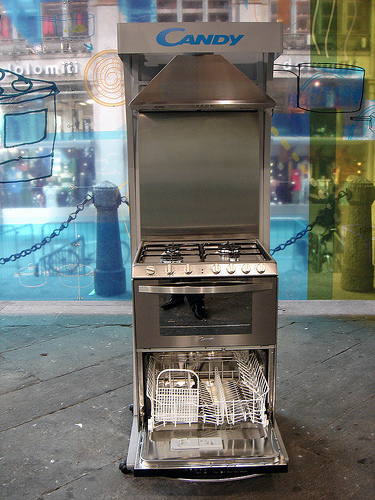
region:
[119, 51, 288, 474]
Multitask kitchen and washing mashine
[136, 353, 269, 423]
White tray of washing machine.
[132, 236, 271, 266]
Stove with four burners.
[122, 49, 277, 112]
Air extraction of a stove.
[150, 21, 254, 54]
Name of multitask household appliance.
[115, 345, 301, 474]
Open dishwasher showing the rack.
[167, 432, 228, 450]
White detergent dispenser.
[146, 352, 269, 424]
White tray of a dishwasher.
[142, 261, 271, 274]
Control panel with seven controls.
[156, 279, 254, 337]
Glass of an oven.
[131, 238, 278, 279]
gas stove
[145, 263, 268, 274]
seven silver color knobs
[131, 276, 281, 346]
stove oven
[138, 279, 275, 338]
silver handle with glass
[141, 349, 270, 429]
white dish rack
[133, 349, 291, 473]
dish rack door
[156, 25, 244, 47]
the word candy written in blue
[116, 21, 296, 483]
a range with all three theaters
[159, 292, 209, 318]
shallow of pant and shoes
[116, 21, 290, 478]
color of this range is gray, black, blue and silver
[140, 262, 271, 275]
row of silver knobs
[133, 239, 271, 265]
4 stovetop burners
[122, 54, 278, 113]
stainless steel rangehood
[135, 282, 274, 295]
long silver pull handle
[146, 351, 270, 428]
white plastic coated dishes basket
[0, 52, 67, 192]
hand drawing of a stove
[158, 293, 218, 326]
reflection of a man's shoes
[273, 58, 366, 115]
hand drawing of a pot on a window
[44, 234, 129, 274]
bicycle laying on the ground outside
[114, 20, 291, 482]
all in one kitchen appliance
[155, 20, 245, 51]
A logo for the company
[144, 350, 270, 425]
The basket of a dishwasher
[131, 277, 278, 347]
A steel oven door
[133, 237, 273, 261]
A range with four burners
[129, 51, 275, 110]
A steel vent hood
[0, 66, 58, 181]
A drawing of a stove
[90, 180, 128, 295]
A post holding a chain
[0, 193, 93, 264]
A black chain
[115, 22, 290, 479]
A combination stove, oven, and dishwasher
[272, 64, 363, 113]
A drawing of a pot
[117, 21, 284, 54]
the word candy painted on kiosk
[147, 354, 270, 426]
a white utensil rack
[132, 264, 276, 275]
long row of control dials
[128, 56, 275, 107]
a metal hood range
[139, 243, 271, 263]
four stove burners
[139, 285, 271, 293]
a metal oven door handle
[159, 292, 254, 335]
a glass oven door window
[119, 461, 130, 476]
a black rolling wheel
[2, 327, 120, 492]
a grey stone lined floor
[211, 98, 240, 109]
a light reflecting on range hood